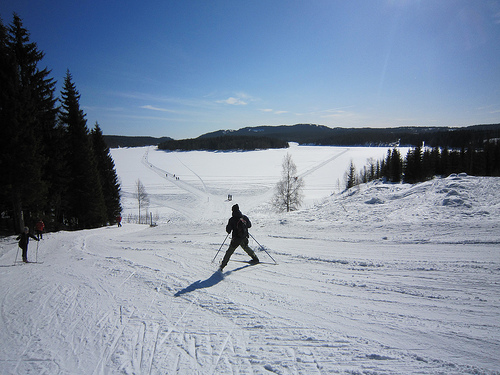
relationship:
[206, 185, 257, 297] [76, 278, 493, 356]
man in snow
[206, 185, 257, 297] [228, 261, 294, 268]
man wearing skis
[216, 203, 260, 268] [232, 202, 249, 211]
man wearing cap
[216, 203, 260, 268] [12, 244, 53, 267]
man with ski poles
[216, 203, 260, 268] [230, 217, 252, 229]
man wearing jacket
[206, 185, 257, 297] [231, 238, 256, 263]
man wearing trousers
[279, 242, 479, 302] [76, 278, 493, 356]
track in snow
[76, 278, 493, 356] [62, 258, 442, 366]
snow covering ground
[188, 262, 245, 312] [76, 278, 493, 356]
shadow on snow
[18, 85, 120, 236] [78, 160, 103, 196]
trees has leaves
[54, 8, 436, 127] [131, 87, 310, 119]
sky has clouds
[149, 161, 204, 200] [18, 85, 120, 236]
people near trees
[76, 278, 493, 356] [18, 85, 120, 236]
snow near trees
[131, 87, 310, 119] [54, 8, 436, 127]
clouds in sky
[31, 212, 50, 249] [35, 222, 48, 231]
skier wearing jacket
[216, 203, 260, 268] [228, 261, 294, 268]
man wearing skis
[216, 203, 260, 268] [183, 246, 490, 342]
man on slope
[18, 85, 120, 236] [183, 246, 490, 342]
trees on slope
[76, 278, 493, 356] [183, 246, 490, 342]
snow on slope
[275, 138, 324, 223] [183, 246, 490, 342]
tree on slope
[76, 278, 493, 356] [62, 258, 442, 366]
snow on ground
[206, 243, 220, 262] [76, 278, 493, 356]
stick in snow